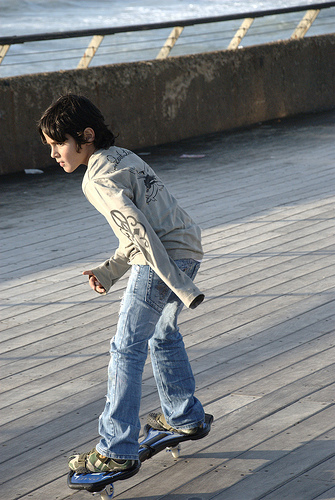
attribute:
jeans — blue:
[94, 258, 207, 460]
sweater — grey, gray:
[82, 146, 207, 310]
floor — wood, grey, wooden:
[3, 110, 335, 498]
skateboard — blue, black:
[66, 413, 217, 499]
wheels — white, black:
[92, 485, 117, 499]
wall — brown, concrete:
[0, 33, 334, 175]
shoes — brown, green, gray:
[66, 445, 138, 475]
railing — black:
[0, 1, 334, 76]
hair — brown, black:
[38, 92, 113, 150]